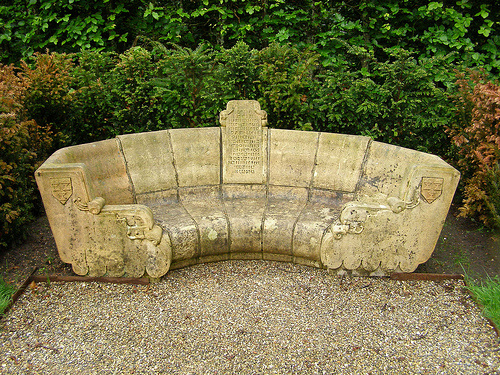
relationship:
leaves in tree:
[347, 77, 388, 106] [14, 27, 495, 216]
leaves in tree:
[367, 69, 418, 100] [348, 42, 467, 139]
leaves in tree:
[408, 96, 456, 126] [308, 47, 466, 144]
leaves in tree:
[327, 70, 391, 122] [309, 61, 455, 132]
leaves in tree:
[307, 62, 382, 126] [240, 46, 384, 131]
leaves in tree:
[168, 49, 217, 98] [163, 51, 251, 128]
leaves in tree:
[428, 25, 476, 50] [387, 4, 487, 75]